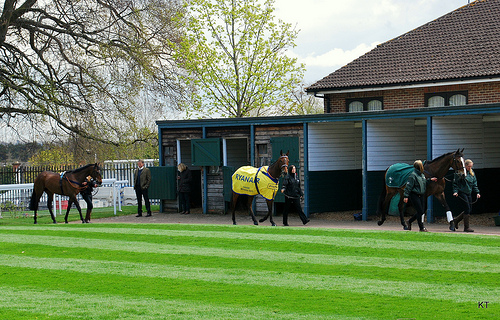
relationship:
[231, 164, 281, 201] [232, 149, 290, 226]
cover on brown horse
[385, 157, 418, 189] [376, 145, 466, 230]
cover on horse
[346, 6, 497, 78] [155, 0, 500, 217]
roof on building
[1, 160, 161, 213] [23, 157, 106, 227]
fence behind horse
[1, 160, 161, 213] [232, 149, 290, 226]
fence behind brown horse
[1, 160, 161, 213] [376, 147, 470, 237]
fence behind horse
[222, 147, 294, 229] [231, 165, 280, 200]
brown horse with cover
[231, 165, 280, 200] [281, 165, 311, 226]
cover being led by person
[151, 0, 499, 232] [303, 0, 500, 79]
building with roof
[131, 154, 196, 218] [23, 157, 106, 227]
men in suits observing last horse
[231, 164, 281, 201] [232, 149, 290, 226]
cover over brown horse